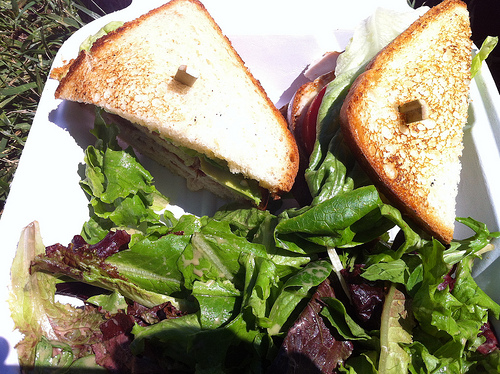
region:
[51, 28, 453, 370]
this is a lunch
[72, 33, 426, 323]
the sandwiches are sliced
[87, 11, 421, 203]
the bread is cut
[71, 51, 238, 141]
the bread is toasted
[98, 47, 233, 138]
the bread is light brown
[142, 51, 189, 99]
the toothpick is dark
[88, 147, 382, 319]
this is a salad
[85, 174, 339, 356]
the salad is dark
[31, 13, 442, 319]
this is a lunch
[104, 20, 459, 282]
the sandwich is cut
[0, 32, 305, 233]
the sandwich is sliced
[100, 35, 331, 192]
the bread is toasted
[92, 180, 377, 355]
this is a salad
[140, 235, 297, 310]
the salad is green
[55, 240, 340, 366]
the salad is purple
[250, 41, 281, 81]
the plate is white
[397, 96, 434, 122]
the pick is wooden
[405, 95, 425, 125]
the pick is tan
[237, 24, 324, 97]
the plate is white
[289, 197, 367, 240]
the spinach is green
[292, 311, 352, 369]
the greens are purple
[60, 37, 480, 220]
sandwhich on the plate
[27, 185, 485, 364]
greens on the plate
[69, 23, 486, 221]
the sandwich is halved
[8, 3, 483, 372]
this is a go plate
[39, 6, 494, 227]
this is a sandwich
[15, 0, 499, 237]
sandwich is cut in half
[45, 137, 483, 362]
greens on the plate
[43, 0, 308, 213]
a half of a sandwich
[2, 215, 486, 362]
a green salad on the plate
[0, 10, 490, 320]
a container on the grass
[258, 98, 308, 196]
the edge of the toast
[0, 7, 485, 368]
food in a container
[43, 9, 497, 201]
two sandwiches on plate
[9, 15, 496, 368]
food on the plate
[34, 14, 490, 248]
sandwich on the plate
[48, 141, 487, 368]
salad on the plate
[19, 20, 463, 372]
a white plate with food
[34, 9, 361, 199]
toasted bread on the sandwich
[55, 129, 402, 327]
lettuce in the salad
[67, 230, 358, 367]
shadow on the salad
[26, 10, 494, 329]
a healthy meal in the background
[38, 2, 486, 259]
two slices of bread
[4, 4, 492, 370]
lettuce next to bread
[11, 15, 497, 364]
bread in a white dish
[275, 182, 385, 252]
the leaf of lettuce is green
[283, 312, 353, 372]
te leaf of lettuce is purple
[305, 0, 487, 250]
lettuce in middle of the bread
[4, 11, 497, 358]
the dish is on the ground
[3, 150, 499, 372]
the lettuce is green and purple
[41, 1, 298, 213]
the sandwich is triangle